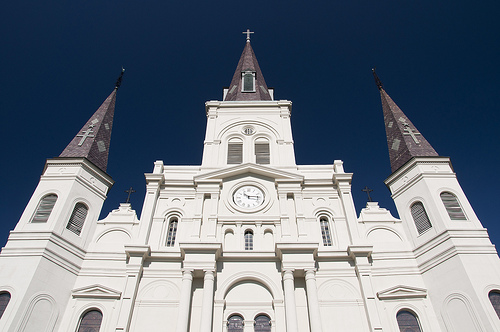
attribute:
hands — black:
[241, 181, 259, 202]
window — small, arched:
[242, 221, 256, 250]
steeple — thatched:
[377, 79, 440, 182]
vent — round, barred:
[235, 117, 256, 137]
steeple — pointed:
[377, 84, 435, 169]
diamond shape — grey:
[382, 132, 407, 161]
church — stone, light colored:
[6, 21, 498, 330]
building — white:
[115, 120, 405, 324]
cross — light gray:
[387, 110, 428, 148]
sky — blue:
[100, 5, 212, 119]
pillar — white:
[165, 272, 221, 327]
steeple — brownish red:
[360, 98, 469, 197]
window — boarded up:
[405, 201, 448, 245]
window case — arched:
[230, 227, 272, 248]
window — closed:
[432, 182, 486, 237]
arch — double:
[214, 298, 273, 329]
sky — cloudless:
[53, 14, 499, 172]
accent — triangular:
[368, 279, 496, 319]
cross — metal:
[111, 180, 151, 219]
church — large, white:
[59, 85, 415, 310]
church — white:
[53, 101, 483, 319]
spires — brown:
[81, 21, 485, 206]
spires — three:
[54, 22, 444, 177]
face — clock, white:
[229, 181, 269, 216]